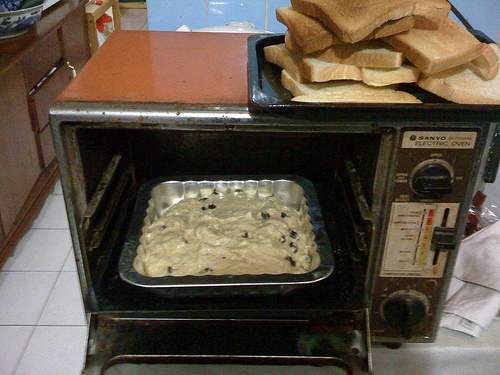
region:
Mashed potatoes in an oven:
[129, 178, 337, 295]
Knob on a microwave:
[380, 274, 442, 347]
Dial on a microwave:
[404, 153, 466, 220]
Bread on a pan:
[238, 1, 451, 135]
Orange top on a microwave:
[84, 12, 236, 120]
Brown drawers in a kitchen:
[13, 41, 100, 198]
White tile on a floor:
[3, 226, 116, 361]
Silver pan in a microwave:
[120, 161, 327, 287]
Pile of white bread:
[267, 6, 467, 112]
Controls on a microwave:
[366, 150, 458, 374]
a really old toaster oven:
[47, 24, 470, 374]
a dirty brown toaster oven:
[32, 25, 461, 371]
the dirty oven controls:
[374, 112, 470, 342]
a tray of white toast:
[247, 4, 497, 118]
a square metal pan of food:
[133, 173, 318, 283]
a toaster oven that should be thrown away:
[49, 26, 458, 364]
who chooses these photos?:
[43, 25, 480, 368]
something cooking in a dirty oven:
[125, 169, 324, 291]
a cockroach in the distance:
[138, 1, 144, 6]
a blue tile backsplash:
[147, 0, 497, 43]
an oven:
[208, 89, 493, 317]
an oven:
[254, 164, 413, 339]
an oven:
[379, 189, 399, 304]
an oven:
[259, 291, 357, 372]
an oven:
[259, 351, 320, 373]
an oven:
[246, 333, 277, 371]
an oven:
[257, 344, 291, 371]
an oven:
[256, 333, 290, 361]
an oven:
[261, 364, 279, 373]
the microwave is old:
[68, 56, 463, 361]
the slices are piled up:
[279, 19, 474, 93]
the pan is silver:
[151, 185, 324, 307]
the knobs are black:
[394, 296, 431, 341]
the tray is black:
[246, 68, 293, 118]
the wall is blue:
[160, 5, 271, 26]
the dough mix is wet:
[158, 207, 297, 276]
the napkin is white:
[465, 249, 490, 339]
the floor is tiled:
[18, 269, 71, 374]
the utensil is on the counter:
[1, 3, 54, 30]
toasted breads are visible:
[243, 13, 368, 138]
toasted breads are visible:
[283, 38, 370, 129]